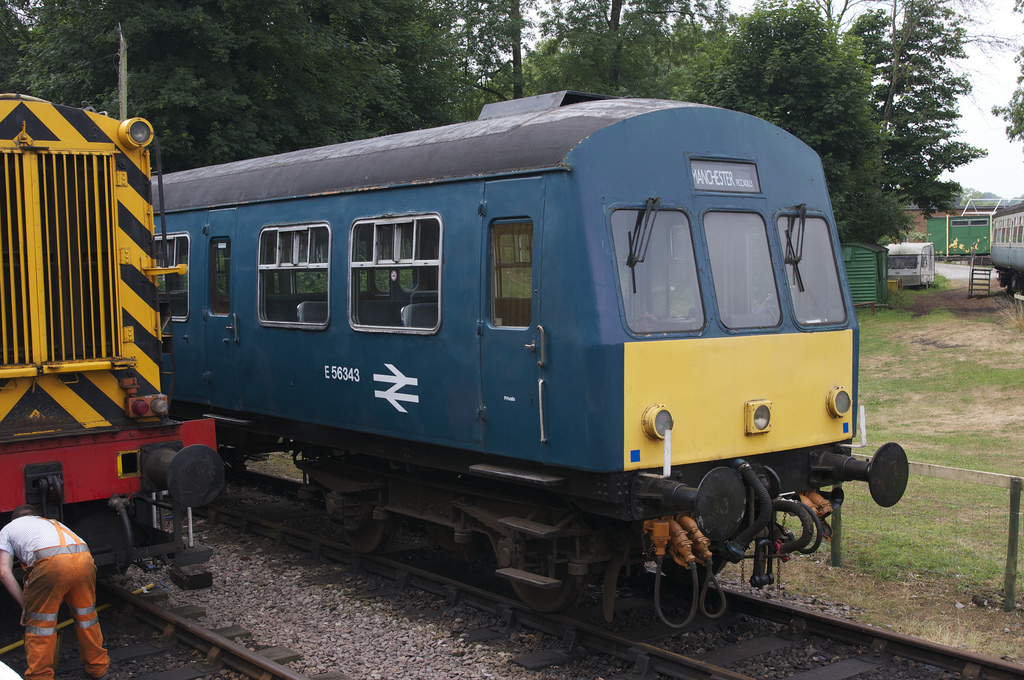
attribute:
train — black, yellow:
[0, 92, 169, 526]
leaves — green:
[717, 5, 877, 215]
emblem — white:
[367, 351, 421, 409]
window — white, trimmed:
[345, 218, 443, 330]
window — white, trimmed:
[256, 218, 330, 327]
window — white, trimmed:
[158, 218, 190, 327]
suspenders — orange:
[31, 506, 86, 545]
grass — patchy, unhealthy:
[822, 272, 1022, 628]